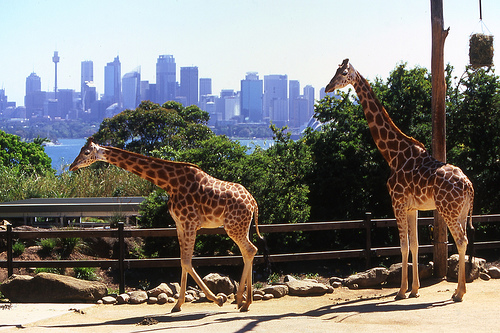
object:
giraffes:
[68, 57, 478, 310]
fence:
[3, 208, 499, 289]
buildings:
[3, 50, 321, 134]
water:
[32, 138, 299, 169]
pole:
[431, 6, 450, 275]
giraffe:
[326, 61, 474, 306]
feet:
[394, 293, 406, 299]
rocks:
[1, 272, 107, 305]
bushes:
[135, 60, 500, 250]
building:
[155, 55, 177, 100]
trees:
[0, 133, 52, 176]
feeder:
[470, 1, 496, 71]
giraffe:
[69, 138, 263, 320]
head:
[64, 137, 103, 171]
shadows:
[55, 291, 462, 326]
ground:
[5, 277, 500, 328]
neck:
[102, 145, 174, 189]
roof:
[156, 54, 176, 62]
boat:
[46, 137, 61, 146]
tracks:
[1, 191, 142, 223]